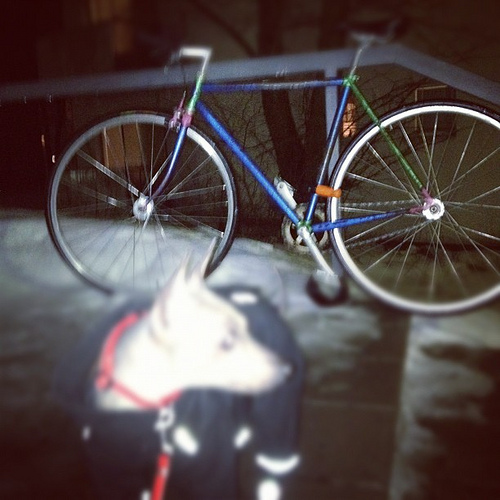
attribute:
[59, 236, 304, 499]
dog — small, white, blurry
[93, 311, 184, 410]
collar — red, nylon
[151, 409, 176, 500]
leash — red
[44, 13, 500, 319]
bicycle — blue, parked, green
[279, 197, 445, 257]
chain — silver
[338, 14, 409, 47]
seat — leather, black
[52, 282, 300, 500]
clothes — dark, black, blue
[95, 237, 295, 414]
hair — short, tan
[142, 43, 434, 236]
frame — blue, metal, triangular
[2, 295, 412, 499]
porch — cement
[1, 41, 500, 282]
railing — silver, metal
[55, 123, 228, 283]
spokes — silver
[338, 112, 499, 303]
spokes — silver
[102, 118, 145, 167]
window — lit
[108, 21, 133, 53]
window — lit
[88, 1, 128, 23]
window — lit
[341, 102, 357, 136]
window — lit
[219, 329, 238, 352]
eye — black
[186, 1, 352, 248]
tree — bare